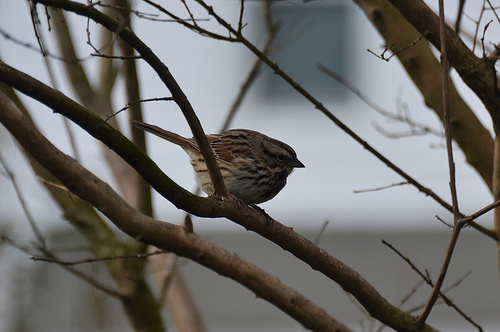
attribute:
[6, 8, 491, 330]
sky — gray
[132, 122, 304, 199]
bird — small, puffy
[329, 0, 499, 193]
branch — small, brown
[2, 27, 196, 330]
tree branch — small, brown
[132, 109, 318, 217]
bird — brown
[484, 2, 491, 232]
house — white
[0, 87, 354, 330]
branch — small, brown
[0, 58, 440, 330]
branch — small, brown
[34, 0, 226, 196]
branch — small, brown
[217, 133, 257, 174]
stripe — brown